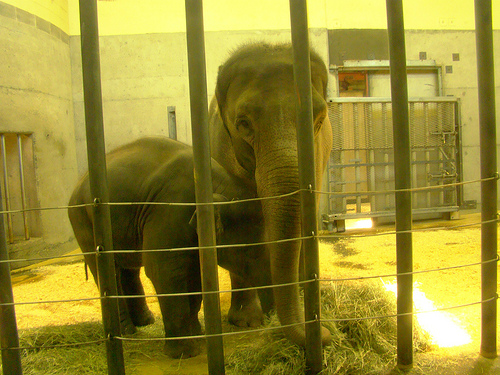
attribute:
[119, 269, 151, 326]
leg — hind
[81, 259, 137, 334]
leg — hind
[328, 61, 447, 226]
door — grey, thick, metal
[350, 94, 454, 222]
fence — metal, grey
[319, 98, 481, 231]
gate — grey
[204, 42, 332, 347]
elephant — standing, older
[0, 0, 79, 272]
wall — grey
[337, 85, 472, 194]
fence — grey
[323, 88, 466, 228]
bars — gray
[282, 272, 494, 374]
greengrass — green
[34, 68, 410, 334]
elephant — big, baby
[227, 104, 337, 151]
eyes — black, little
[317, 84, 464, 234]
gate — metal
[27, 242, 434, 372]
straw — bunch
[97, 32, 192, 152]
walls — grey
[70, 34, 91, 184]
walls — grey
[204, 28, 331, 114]
walls — grey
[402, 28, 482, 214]
walls — grey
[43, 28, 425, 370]
elephants — grey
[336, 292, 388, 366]
hay — brown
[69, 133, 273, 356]
elephant — baby, standing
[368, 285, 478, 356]
light — glaring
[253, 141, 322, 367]
trunk — large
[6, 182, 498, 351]
wire — gray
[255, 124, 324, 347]
trunk — long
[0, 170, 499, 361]
wires — grey